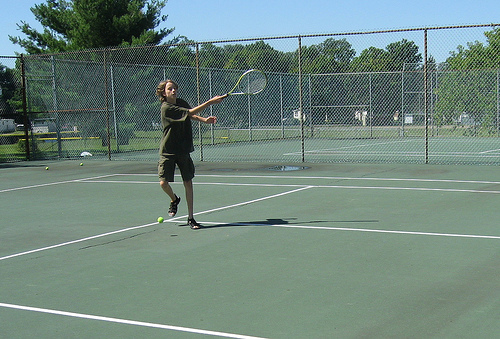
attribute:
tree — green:
[15, 1, 183, 42]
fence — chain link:
[22, 24, 498, 182]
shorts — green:
[156, 152, 198, 184]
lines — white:
[3, 170, 497, 337]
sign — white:
[265, 180, 425, 305]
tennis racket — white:
[220, 64, 264, 101]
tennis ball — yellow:
[155, 215, 167, 224]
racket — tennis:
[210, 64, 275, 105]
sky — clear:
[166, 5, 438, 31]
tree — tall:
[34, 3, 152, 128]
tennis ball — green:
[157, 217, 167, 223]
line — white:
[300, 182, 499, 197]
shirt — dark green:
[152, 95, 199, 158]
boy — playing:
[148, 73, 222, 231]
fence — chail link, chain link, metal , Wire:
[10, 20, 499, 165]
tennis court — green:
[6, 141, 497, 333]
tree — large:
[9, 0, 189, 155]